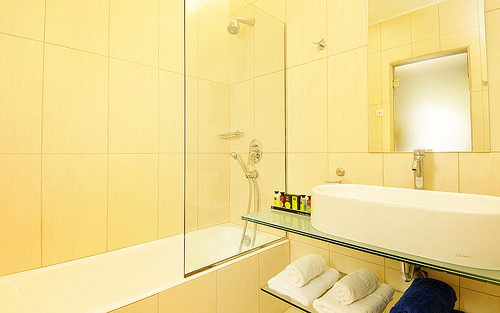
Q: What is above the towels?
A: Bathroom sink.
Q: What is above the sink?
A: Vanity mirror.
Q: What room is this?
A: Bathroom.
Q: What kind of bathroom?
A: Hotel.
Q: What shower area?
A: Bathtub.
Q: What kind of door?
A: Glass.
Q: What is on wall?
A: Mirror.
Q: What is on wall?
A: Knobs.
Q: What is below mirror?
A: Sink.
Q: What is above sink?
A: Mirror.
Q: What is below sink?
A: Towels.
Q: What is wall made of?
A: Tile.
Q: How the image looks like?
A: Clean.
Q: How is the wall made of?
A: Tiles.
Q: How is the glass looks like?
A: Transparent.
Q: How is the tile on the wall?
A: White.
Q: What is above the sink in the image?
A: Mirror.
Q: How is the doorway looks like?
A: Good.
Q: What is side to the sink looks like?
A: Bathtub.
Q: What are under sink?
A: Towel.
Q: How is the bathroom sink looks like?
A: Good.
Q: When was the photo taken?
A: Daytime.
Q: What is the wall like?
A: Tiled.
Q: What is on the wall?
A: A mirror.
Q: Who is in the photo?
A: Nobody.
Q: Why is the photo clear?
A: The area is lit.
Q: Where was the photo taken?
A: In the bathroom.